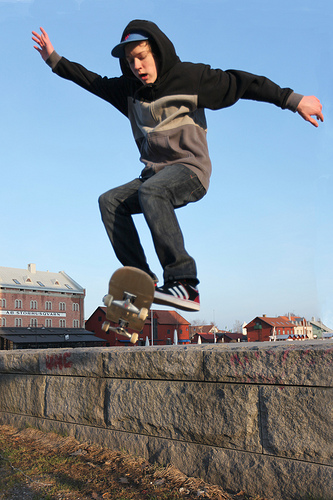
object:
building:
[0, 264, 85, 330]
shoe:
[154, 280, 200, 311]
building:
[243, 315, 297, 342]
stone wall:
[0, 349, 333, 499]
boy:
[32, 20, 324, 311]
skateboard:
[101, 266, 155, 344]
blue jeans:
[98, 163, 206, 286]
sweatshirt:
[45, 19, 304, 192]